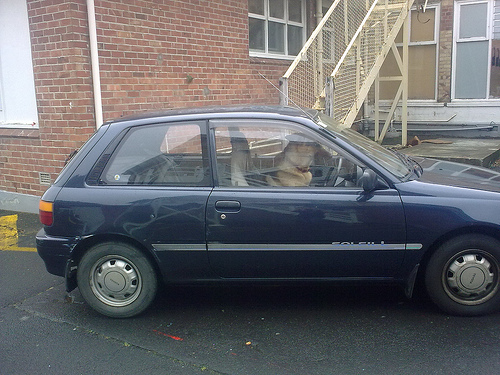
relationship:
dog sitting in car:
[259, 134, 331, 187] [34, 104, 499, 318]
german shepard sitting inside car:
[259, 134, 331, 187] [34, 104, 499, 318]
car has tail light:
[34, 104, 499, 318] [38, 200, 53, 225]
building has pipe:
[0, 0, 498, 214] [84, 1, 106, 128]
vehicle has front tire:
[34, 104, 499, 318] [427, 234, 499, 314]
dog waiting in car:
[259, 134, 331, 187] [34, 104, 499, 318]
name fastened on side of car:
[331, 238, 387, 248] [34, 104, 499, 318]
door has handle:
[201, 117, 412, 283] [215, 198, 242, 213]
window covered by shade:
[376, 8, 438, 103] [411, 10, 435, 43]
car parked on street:
[34, 104, 499, 318] [2, 211, 500, 373]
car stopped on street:
[34, 104, 499, 318] [2, 211, 500, 373]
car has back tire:
[34, 104, 499, 318] [76, 243, 156, 317]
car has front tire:
[34, 104, 499, 318] [427, 234, 499, 314]